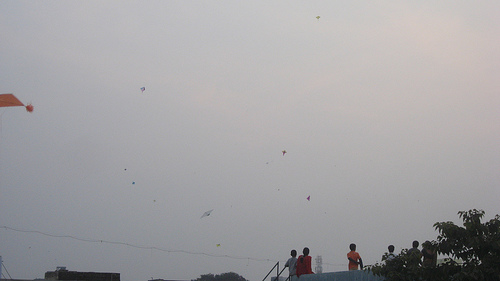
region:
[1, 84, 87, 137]
red kite in sky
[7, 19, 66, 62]
white clouds in blue sky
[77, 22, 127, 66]
white clouds in blue sky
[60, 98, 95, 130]
white clouds in blue sky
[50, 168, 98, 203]
white clouds in blue sky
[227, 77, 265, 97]
white clouds in blue sky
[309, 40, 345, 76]
white clouds in blue sky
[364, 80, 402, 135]
white clouds in blue sky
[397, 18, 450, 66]
white clouds in blue sky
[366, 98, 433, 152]
white clouds in blue sky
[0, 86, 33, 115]
orange kite flying on left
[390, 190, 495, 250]
green tree growing on right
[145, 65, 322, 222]
kites flying over head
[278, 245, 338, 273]
two boys on rail flying kites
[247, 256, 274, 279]
small rails on stairs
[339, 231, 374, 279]
boy in orange on platform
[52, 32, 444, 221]
gray overcast sky above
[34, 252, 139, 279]
top of square building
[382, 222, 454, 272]
three people on right flying kites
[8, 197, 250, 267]
power line in background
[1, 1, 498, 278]
A grey cloudy sky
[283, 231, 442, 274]
A group of children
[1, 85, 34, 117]
A kite in the sky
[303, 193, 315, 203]
A kite in the sky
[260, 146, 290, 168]
A kite in the sky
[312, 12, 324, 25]
A kite in the sky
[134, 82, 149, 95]
A kite in the sky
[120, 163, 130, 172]
A kite in the sky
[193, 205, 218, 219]
A kite in the sky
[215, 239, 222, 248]
A kite in the sky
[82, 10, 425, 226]
kites flying in the sky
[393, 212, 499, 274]
trees with branches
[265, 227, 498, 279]
people are sitting in the place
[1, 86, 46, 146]
orange color kite flying in the sky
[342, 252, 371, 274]
a boy wearing orange color t-shirt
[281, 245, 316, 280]
two of them sitting together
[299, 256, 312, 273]
ornage color dress of the woman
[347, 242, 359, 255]
head of the boy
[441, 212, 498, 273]
leaves and branches of the tree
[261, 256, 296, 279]
boy holding metal post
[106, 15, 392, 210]
lot of kites flying in the sky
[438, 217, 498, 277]
green color trees with branches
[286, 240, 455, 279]
lot of people seeing the kite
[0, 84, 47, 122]
orange color kite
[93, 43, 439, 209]
sky with clouds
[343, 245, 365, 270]
a boy wearing orange color shirt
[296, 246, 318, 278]
a girl wearing orange color dress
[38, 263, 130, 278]
top of the building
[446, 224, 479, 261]
leaves in the tree